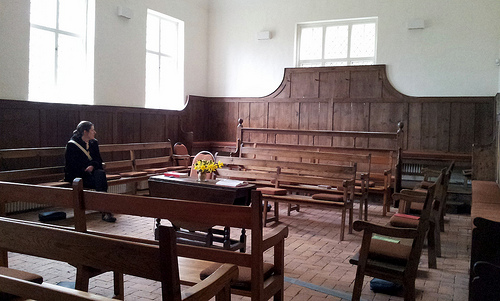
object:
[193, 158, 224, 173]
flowers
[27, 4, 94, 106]
window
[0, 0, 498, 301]
photo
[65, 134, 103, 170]
jacket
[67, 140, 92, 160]
strap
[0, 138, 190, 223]
bench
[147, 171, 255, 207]
table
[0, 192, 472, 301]
floor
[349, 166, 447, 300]
chair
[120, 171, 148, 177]
cushion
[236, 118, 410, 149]
railing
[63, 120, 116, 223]
woman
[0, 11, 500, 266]
room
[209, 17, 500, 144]
wall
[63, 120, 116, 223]
person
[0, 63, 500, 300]
church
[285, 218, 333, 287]
tiles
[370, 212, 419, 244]
books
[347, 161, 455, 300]
chairs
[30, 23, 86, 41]
lines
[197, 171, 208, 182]
vase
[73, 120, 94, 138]
hair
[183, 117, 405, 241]
benches